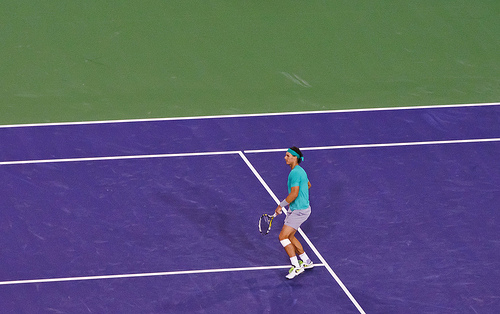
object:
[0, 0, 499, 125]
bounds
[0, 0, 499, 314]
court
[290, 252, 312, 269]
sock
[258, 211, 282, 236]
racket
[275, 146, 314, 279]
man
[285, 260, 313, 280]
shoe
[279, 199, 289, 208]
gray wristband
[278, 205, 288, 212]
wristband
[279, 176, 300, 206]
arm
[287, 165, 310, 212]
shirt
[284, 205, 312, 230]
shorts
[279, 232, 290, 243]
knee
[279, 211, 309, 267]
leg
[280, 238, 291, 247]
band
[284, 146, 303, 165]
head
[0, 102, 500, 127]
line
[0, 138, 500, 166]
line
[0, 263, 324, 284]
line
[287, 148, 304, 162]
headband